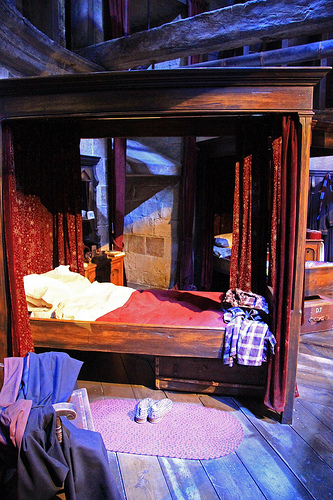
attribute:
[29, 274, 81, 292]
pillow — white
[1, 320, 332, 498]
floor — wooden, dark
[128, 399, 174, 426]
shoes — boy's shoes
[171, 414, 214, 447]
rug — red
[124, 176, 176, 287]
wall — stony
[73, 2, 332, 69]
beam — wooden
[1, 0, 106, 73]
beam — wooden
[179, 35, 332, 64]
beam — wooden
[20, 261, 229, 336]
sheets — white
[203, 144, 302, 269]
curtains — drawn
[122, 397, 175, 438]
shoes — rubber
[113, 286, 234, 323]
sheet — red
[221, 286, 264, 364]
robe — plaid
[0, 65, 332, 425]
canopy bed — antique